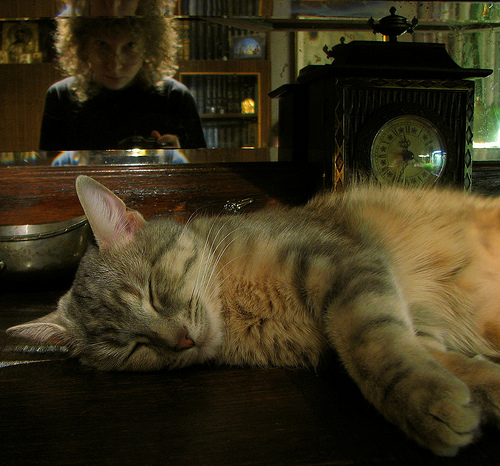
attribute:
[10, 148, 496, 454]
cat — sleepig, iside, laig, laiig, sleeping, gra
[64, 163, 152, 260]
ear — pink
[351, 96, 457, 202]
clock — sittig, white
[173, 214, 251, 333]
whiskers — white, log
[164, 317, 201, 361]
nose — pink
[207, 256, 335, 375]
bib — brown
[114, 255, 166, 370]
eyes — slitted, closed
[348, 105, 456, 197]
trim — decorative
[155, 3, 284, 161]
book shelf — large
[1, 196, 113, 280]
bowl — silver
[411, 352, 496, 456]
paws — striped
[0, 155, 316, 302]
dresser — brow